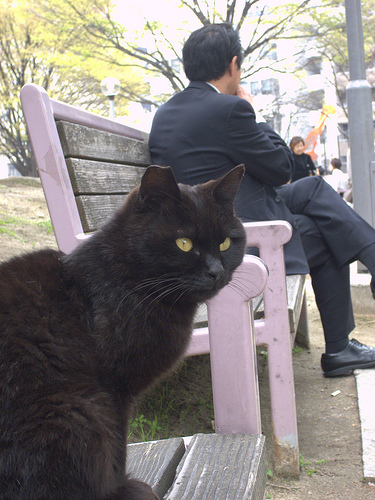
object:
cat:
[0, 162, 246, 497]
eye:
[173, 237, 193, 254]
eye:
[218, 235, 232, 253]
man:
[148, 21, 374, 376]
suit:
[148, 82, 373, 341]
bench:
[20, 79, 300, 475]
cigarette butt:
[330, 387, 342, 397]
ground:
[303, 283, 375, 498]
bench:
[0, 253, 267, 499]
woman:
[288, 135, 319, 181]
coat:
[290, 153, 320, 178]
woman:
[328, 153, 349, 191]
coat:
[326, 167, 346, 193]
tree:
[2, 1, 161, 96]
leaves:
[43, 38, 130, 77]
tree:
[249, 2, 374, 76]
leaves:
[320, 22, 346, 65]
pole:
[344, 0, 374, 274]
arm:
[241, 218, 293, 243]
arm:
[236, 252, 267, 301]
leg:
[267, 327, 300, 481]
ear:
[138, 164, 182, 203]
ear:
[216, 162, 247, 203]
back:
[18, 89, 156, 231]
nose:
[209, 263, 228, 281]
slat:
[183, 432, 263, 498]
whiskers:
[114, 272, 276, 324]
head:
[181, 23, 242, 83]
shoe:
[320, 341, 373, 379]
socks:
[326, 340, 346, 352]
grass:
[136, 407, 173, 441]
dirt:
[185, 367, 206, 427]